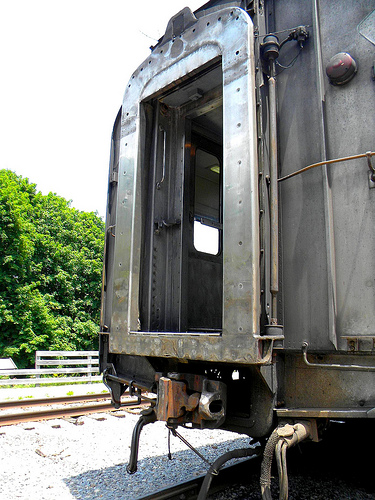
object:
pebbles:
[208, 449, 211, 452]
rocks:
[90, 485, 102, 493]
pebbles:
[0, 382, 105, 404]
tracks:
[0, 393, 147, 422]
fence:
[0, 346, 101, 386]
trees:
[0, 168, 108, 380]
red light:
[321, 47, 365, 91]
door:
[140, 54, 228, 337]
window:
[193, 220, 222, 256]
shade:
[191, 151, 226, 228]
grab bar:
[154, 120, 170, 195]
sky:
[0, 0, 207, 221]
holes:
[140, 67, 144, 71]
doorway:
[92, 6, 271, 370]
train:
[98, 0, 375, 497]